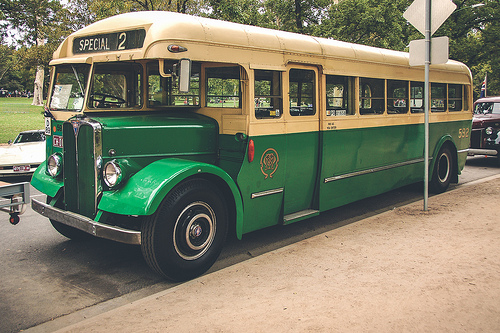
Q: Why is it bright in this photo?
A: It's daytime.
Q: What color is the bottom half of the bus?
A: Green.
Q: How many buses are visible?
A: One.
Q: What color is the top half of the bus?
A: Off-white.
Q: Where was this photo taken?
A: On the street.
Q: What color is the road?
A: Gray.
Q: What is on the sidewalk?
A: A road sign.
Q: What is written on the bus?
A: Special 2.